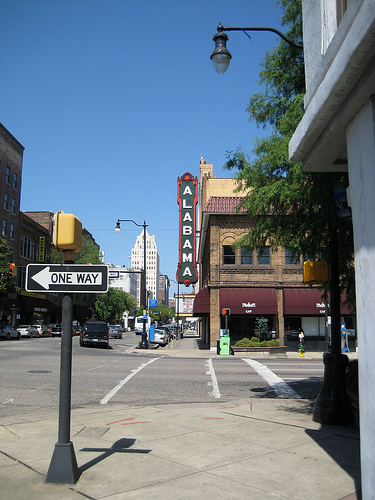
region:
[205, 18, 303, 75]
A beautiful light is fixed in the wall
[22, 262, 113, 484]
A black pole with street sign board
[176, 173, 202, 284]
A board describe a business name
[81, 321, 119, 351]
Car is about to start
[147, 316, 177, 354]
Lot of vehicles are parked in the road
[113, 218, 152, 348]
A big light pole standing in the street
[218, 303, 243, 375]
Signal pole glowing red light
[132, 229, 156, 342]
A historic white color building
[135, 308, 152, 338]
A bus is moving in the road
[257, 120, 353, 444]
Tree with green leave is behind the building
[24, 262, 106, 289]
Black rectangular metal sign with a white arrow and black text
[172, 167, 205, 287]
Tall red bordered black sign with white letters reading Alabama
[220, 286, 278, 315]
Red canopy of a building with white letters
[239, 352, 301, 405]
White line painted onto gray asphalt with shade on the bottom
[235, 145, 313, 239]
Dark green thick leaves from a tree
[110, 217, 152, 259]
Black metal street lamp with a yellow light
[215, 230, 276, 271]
Row of windows in a light tan colored building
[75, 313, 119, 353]
Black car with red lights driving down the street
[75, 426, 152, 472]
Cross shaped shadow on the gray sidewalk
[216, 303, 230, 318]
Red light on the cross walk indicator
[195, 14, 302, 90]
black vintage style street lamp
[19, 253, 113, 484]
one way street sign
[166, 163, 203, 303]
red and green alabama sign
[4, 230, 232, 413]
empty intersection in a small city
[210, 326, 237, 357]
green newspaper distributing box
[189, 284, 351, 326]
burgundy building awnings with white letters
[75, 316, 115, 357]
black suv turning onto a street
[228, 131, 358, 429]
small tree near an intersection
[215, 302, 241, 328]
Don't walk sign illuminated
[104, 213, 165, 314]
pristine white building in the distance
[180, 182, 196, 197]
white letter on a sign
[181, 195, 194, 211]
white letter on a sign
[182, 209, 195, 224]
white letter on a sign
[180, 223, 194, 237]
white letter on a sign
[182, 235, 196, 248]
white letter on a sign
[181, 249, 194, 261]
white letter on a sign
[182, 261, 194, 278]
white letter on a sign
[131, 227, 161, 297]
white building in a city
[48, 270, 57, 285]
black letter on a sign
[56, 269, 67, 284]
black letter on a sign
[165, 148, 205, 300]
A large sign on a building that says "Alabama"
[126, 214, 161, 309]
A white skyscraper with a pointed top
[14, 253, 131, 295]
A sign with an arrow reading "one way"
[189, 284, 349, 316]
A maroon awning with white text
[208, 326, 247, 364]
A light green newspaper box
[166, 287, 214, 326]
A white marquee with yellow trim and red text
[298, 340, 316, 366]
A yellow and green fire hydrant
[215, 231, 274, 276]
A row of three windows with arched decorations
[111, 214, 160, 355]
A black streetlamp with a round white bulb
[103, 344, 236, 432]
A white crosswalk